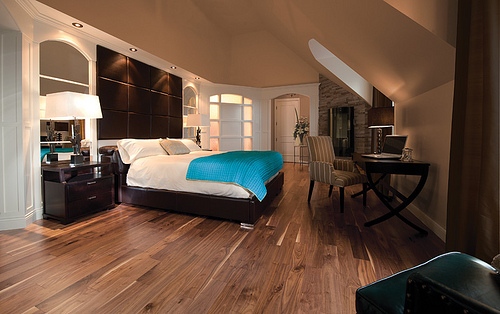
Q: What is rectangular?
A: Lamp shade.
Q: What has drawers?
A: Night stand.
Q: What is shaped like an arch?
A: Wall mirror.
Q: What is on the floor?
A: Long planks.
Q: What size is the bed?
A: King size.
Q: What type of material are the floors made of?
A: Wood.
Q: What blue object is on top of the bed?
A: Blanket.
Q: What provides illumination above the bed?
A: Recessed lights.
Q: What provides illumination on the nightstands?
A: Lamps.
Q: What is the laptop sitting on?
A: Desk.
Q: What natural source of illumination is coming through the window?
A: Sunlight.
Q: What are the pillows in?
A: Pillow cases.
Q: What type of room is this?
A: Bedroom.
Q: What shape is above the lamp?
A: Arch.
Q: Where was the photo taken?
A: A bedroom.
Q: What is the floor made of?
A: Wood.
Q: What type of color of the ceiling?
A: Brown.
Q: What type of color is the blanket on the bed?
A: Light blue.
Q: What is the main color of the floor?
A: Brown.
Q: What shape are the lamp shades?
A: Square.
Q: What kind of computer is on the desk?
A: A laptop.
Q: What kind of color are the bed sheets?
A: White.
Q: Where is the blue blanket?
A: On the bed.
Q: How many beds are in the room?
A: 1.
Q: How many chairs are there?
A: 1.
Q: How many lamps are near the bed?
A: 1.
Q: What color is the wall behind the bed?
A: Brown.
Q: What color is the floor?
A: Brown.